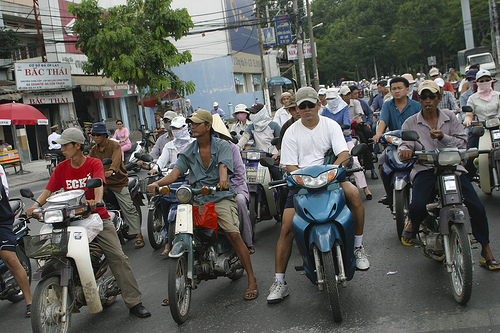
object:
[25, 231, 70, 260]
basket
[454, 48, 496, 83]
truck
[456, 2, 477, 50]
pole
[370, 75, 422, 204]
man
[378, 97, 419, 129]
shirt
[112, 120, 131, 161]
person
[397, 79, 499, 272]
person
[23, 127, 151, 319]
person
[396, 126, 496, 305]
bike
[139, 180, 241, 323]
bike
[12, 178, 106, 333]
bike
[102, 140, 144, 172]
bike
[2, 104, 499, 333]
street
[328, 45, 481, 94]
back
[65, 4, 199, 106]
tree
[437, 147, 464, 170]
ground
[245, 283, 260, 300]
sandles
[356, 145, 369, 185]
ground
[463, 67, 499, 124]
person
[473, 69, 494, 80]
white hat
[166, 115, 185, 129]
white hat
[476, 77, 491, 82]
sunglasses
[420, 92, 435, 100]
sunglasses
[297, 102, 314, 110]
sunglasses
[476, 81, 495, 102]
pink cloth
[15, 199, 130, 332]
scooter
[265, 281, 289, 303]
tennis shoe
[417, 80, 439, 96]
khaki cap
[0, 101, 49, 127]
plate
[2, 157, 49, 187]
sidewalk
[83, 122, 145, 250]
person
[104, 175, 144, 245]
bike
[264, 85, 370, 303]
person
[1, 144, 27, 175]
box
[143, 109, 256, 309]
rider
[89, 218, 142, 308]
pants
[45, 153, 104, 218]
shirt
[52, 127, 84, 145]
cap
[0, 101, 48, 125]
umbrella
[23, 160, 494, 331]
sidewalk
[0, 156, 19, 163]
stripe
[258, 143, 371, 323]
bike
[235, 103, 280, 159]
person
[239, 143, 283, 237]
bike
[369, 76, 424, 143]
person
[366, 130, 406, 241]
bike